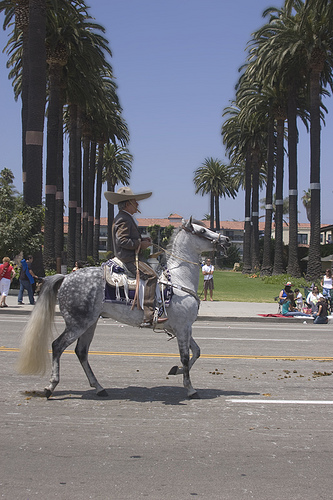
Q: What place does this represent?
A: It represents the street.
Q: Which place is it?
A: It is a street.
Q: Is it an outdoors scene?
A: Yes, it is outdoors.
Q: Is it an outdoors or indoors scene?
A: It is outdoors.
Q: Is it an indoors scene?
A: No, it is outdoors.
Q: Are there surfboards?
A: No, there are no surfboards.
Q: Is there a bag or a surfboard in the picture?
A: No, there are no surfboards or bags.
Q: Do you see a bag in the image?
A: No, there are no bags.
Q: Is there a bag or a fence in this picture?
A: No, there are no bags or fences.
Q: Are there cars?
A: No, there are no cars.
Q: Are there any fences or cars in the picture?
A: No, there are no cars or fences.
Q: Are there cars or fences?
A: No, there are no cars or fences.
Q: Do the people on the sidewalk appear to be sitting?
A: Yes, the people are sitting.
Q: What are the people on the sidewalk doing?
A: The people are sitting.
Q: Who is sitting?
A: The people are sitting.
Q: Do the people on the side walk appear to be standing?
A: No, the people are sitting.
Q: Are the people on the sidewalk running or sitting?
A: The people are sitting.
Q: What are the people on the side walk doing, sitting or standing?
A: The people are sitting.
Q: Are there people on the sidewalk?
A: Yes, there are people on the sidewalk.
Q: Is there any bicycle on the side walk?
A: No, there are people on the side walk.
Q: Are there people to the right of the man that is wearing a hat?
A: Yes, there are people to the right of the man.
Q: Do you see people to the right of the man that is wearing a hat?
A: Yes, there are people to the right of the man.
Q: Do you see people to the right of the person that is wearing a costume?
A: Yes, there are people to the right of the man.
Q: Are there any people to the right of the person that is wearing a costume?
A: Yes, there are people to the right of the man.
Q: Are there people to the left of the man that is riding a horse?
A: No, the people are to the right of the man.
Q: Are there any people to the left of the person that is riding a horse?
A: No, the people are to the right of the man.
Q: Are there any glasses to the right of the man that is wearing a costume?
A: No, there are people to the right of the man.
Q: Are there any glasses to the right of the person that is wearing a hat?
A: No, there are people to the right of the man.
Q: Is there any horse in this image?
A: Yes, there is a horse.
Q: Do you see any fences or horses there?
A: Yes, there is a horse.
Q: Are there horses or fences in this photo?
A: Yes, there is a horse.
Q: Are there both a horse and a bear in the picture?
A: No, there is a horse but no bears.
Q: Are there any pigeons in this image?
A: No, there are no pigeons.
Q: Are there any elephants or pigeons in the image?
A: No, there are no pigeons or elephants.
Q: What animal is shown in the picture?
A: The animal is a horse.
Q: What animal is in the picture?
A: The animal is a horse.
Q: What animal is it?
A: The animal is a horse.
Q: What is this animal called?
A: This is a horse.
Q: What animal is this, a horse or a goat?
A: This is a horse.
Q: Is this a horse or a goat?
A: This is a horse.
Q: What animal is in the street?
A: The horse is in the street.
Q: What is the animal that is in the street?
A: The animal is a horse.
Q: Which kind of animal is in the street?
A: The animal is a horse.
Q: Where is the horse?
A: The horse is in the street.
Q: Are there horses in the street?
A: Yes, there is a horse in the street.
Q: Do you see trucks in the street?
A: No, there is a horse in the street.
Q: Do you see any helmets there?
A: No, there are no helmets.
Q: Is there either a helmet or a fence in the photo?
A: No, there are no helmets or fences.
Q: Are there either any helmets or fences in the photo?
A: No, there are no helmets or fences.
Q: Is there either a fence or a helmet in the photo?
A: No, there are no helmets or fences.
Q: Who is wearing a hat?
A: The man is wearing a hat.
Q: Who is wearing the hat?
A: The man is wearing a hat.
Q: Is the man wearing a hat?
A: Yes, the man is wearing a hat.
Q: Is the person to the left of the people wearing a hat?
A: Yes, the man is wearing a hat.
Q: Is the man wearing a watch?
A: No, the man is wearing a hat.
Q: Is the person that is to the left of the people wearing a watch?
A: No, the man is wearing a hat.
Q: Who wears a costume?
A: The man wears a costume.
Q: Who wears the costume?
A: The man wears a costume.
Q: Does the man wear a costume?
A: Yes, the man wears a costume.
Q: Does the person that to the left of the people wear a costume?
A: Yes, the man wears a costume.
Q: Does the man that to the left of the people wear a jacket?
A: No, the man wears a costume.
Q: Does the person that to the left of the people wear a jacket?
A: No, the man wears a costume.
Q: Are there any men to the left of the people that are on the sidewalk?
A: Yes, there is a man to the left of the people.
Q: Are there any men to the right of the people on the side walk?
A: No, the man is to the left of the people.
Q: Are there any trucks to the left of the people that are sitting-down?
A: No, there is a man to the left of the people.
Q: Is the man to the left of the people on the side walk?
A: Yes, the man is to the left of the people.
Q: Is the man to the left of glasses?
A: No, the man is to the left of the people.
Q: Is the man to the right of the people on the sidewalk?
A: No, the man is to the left of the people.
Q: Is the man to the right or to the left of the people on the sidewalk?
A: The man is to the left of the people.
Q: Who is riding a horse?
A: The man is riding a horse.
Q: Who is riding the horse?
A: The man is riding a horse.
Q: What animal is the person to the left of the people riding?
A: The man is riding a horse.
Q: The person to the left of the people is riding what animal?
A: The man is riding a horse.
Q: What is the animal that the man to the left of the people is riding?
A: The animal is a horse.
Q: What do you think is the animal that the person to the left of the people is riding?
A: The animal is a horse.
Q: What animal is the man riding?
A: The man is riding a horse.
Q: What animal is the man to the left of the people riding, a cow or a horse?
A: The man is riding a horse.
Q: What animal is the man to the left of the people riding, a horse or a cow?
A: The man is riding a horse.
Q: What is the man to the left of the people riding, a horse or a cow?
A: The man is riding a horse.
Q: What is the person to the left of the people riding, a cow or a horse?
A: The man is riding a horse.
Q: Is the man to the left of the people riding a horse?
A: Yes, the man is riding a horse.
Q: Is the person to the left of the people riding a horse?
A: Yes, the man is riding a horse.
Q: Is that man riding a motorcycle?
A: No, the man is riding a horse.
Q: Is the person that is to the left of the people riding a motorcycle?
A: No, the man is riding a horse.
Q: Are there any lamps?
A: No, there are no lamps.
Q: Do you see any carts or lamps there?
A: No, there are no lamps or carts.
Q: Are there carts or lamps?
A: No, there are no lamps or carts.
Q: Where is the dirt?
A: The dirt is on the street.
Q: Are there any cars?
A: No, there are no cars.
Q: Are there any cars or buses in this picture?
A: No, there are no cars or buses.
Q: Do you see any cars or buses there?
A: No, there are no cars or buses.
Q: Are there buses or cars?
A: No, there are no cars or buses.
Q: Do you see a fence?
A: No, there are no fences.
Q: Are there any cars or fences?
A: No, there are no fences or cars.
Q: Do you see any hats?
A: Yes, there is a hat.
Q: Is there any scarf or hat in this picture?
A: Yes, there is a hat.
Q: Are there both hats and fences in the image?
A: No, there is a hat but no fences.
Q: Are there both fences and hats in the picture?
A: No, there is a hat but no fences.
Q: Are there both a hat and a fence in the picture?
A: No, there is a hat but no fences.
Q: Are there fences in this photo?
A: No, there are no fences.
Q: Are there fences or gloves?
A: No, there are no fences or gloves.